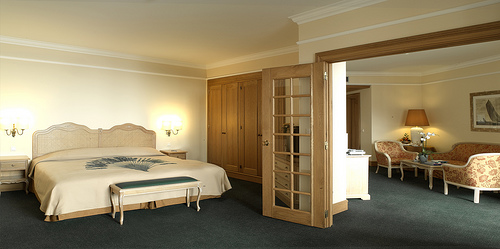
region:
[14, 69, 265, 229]
a king size bed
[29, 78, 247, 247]
a large king size bed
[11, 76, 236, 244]
a king size bed made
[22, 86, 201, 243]
a king size bed in room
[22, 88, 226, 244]
a king size head board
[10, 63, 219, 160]
two lights on wall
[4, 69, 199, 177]
lights on the wall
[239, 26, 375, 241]
an open door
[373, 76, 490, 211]
a light on a table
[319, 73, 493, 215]
a sitting area room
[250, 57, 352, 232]
door leading to other room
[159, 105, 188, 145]
the light is on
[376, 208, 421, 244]
the floor has carpet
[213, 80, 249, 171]
the doors of the closet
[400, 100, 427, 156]
the lamp is on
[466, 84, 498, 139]
painting on the wall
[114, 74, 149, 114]
the walls are white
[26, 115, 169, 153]
the headboard is against the wall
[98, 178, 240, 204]
green is on top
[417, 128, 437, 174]
flowers on table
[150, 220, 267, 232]
gray carpet on the floor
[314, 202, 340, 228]
hinges on the brown door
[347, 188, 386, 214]
foot of white dresser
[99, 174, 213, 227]
tan and gray foot table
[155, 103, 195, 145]
light holder on the wall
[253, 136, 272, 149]
gold handle on the door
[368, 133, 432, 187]
tan and yellow divan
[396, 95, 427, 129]
gold lampshade on the lamp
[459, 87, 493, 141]
large picture on the wall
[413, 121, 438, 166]
gray vase with white flowers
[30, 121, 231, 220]
a king sized bed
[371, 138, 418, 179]
an orange padded chair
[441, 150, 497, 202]
an orange padded chair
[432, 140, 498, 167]
an orange padded couch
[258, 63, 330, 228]
a opened door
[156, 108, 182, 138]
wall mounted bedroom lights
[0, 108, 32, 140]
wall mounted bedroom lights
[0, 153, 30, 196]
a light brown bed side table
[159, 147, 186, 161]
a light brown bed side table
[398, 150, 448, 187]
a wooden coffee table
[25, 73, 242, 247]
a bed in a room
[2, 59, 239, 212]
two lights on the wall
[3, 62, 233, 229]
a bed with a head board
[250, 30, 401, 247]
a door that is open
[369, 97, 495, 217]
a sitting area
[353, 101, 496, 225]
chairs and a table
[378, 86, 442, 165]
a lap on a table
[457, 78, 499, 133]
a picture on the wall